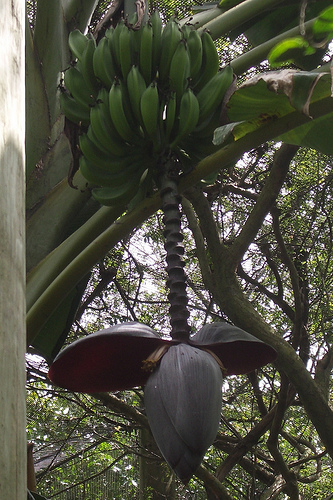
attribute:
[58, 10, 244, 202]
bananas — green, unripened, unripeded, group, large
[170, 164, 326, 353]
branch — brown, twisting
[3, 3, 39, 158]
sun — shining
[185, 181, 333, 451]
wood — long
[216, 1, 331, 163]
leaves — large, green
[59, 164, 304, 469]
part — pod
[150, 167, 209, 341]
stem — ribbed, thick, spiny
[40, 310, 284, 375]
petals — large, brown, downward, dark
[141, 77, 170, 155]
banana — single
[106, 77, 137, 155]
banana — single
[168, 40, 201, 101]
banana — single